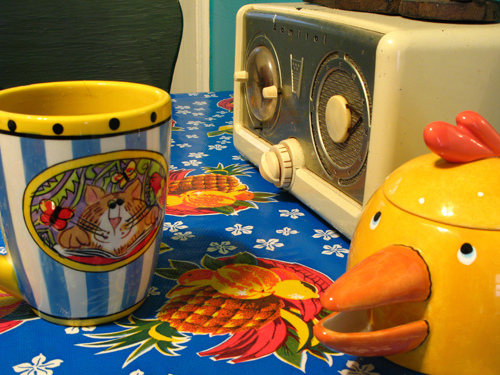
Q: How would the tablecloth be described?
A: Colorful.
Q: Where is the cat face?
A: On the mug.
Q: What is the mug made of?
A: Ceramic.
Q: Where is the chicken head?
A: Lower right.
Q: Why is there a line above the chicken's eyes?
A: Top of the head is a lid.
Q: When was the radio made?
A: At least 50 years ago.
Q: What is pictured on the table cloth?
A: Flowers and fruit.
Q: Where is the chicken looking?
A: Up.